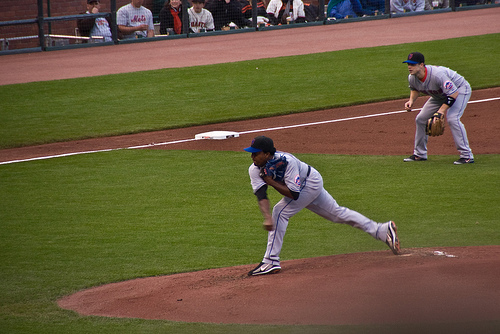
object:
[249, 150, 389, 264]
uniform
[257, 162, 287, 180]
glove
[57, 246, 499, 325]
mount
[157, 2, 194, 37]
woman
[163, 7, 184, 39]
scarf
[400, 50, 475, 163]
baseball player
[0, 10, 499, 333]
field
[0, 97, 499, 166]
foul line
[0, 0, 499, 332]
stadium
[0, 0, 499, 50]
dugout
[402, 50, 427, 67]
baseball cap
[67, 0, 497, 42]
players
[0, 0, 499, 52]
row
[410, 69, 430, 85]
collar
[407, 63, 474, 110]
shirt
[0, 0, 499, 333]
ball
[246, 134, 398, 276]
baseball player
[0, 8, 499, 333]
infield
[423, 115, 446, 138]
baseball glove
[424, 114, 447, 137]
hand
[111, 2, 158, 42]
man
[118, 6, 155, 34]
t-shirt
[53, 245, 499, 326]
pitcher's mound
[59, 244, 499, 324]
dirt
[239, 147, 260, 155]
brim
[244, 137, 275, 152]
baseball cap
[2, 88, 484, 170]
path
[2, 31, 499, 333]
grass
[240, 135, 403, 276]
pitcher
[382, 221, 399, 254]
shoe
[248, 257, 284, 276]
shoe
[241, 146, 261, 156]
rim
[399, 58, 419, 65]
rim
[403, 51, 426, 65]
cap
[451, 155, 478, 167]
foot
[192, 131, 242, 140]
base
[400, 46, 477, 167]
player